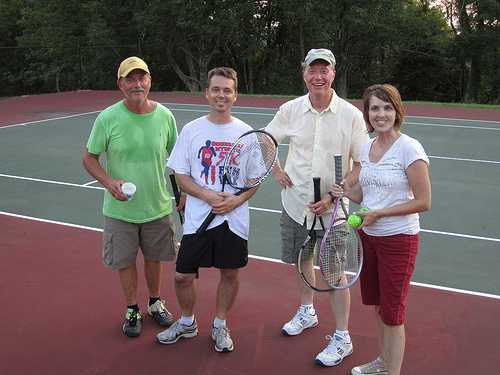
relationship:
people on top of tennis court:
[82, 47, 431, 373] [0, 90, 499, 374]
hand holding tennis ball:
[355, 209, 377, 230] [346, 213, 362, 228]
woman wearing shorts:
[332, 82, 432, 374] [357, 225, 420, 326]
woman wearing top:
[332, 82, 432, 374] [358, 134, 428, 238]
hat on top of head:
[304, 47, 336, 67] [298, 48, 338, 95]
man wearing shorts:
[155, 66, 266, 352] [176, 220, 249, 267]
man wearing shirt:
[81, 54, 188, 338] [86, 98, 180, 225]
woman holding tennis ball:
[332, 82, 432, 374] [346, 213, 362, 228]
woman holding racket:
[332, 82, 432, 374] [318, 152, 365, 291]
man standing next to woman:
[261, 47, 370, 367] [332, 82, 432, 374]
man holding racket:
[261, 47, 370, 367] [295, 176, 342, 292]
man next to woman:
[261, 47, 370, 367] [332, 82, 432, 374]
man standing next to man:
[155, 66, 266, 352] [81, 54, 188, 338]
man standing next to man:
[155, 66, 266, 352] [261, 47, 370, 367]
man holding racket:
[155, 66, 266, 352] [194, 128, 279, 234]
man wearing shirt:
[155, 66, 266, 352] [164, 115, 268, 240]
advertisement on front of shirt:
[197, 139, 244, 190] [164, 115, 268, 240]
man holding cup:
[81, 54, 188, 338] [120, 180, 137, 202]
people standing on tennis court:
[82, 47, 431, 373] [0, 90, 499, 374]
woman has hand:
[332, 82, 432, 374] [355, 209, 377, 230]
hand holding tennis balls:
[355, 209, 377, 230] [349, 206, 369, 228]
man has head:
[261, 47, 370, 367] [298, 48, 338, 95]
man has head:
[81, 54, 188, 338] [115, 56, 153, 104]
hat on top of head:
[116, 56, 150, 80] [115, 56, 153, 104]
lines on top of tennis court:
[1, 100, 499, 300] [0, 90, 499, 374]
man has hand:
[81, 54, 188, 338] [106, 176, 129, 203]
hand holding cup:
[106, 176, 129, 203] [120, 180, 137, 202]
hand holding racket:
[355, 209, 377, 230] [318, 152, 365, 291]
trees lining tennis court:
[0, 1, 498, 106] [0, 90, 499, 374]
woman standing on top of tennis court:
[332, 82, 432, 374] [0, 90, 499, 374]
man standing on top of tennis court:
[155, 66, 266, 352] [0, 90, 499, 374]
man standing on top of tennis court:
[81, 54, 188, 338] [0, 90, 499, 374]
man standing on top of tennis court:
[261, 47, 370, 367] [0, 90, 499, 374]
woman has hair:
[332, 82, 432, 374] [361, 82, 405, 135]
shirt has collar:
[266, 87, 371, 230] [299, 85, 340, 114]